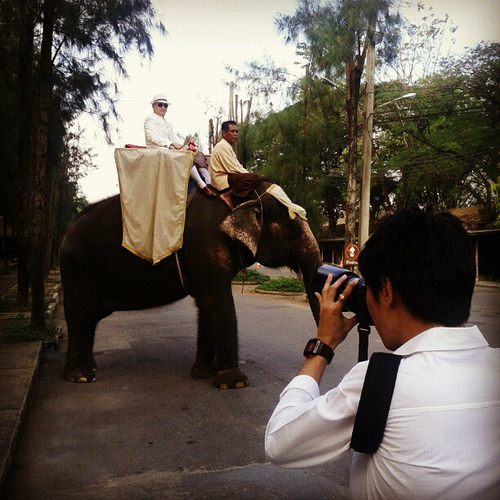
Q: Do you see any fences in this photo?
A: No, there are no fences.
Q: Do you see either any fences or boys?
A: No, there are no fences or boys.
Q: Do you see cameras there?
A: Yes, there is a camera.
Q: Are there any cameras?
A: Yes, there is a camera.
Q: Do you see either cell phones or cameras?
A: Yes, there is a camera.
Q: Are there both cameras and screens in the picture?
A: No, there is a camera but no screens.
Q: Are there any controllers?
A: No, there are no controllers.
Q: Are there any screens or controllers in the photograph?
A: No, there are no controllers or screens.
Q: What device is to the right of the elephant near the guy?
A: The device is a camera.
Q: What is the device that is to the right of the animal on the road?
A: The device is a camera.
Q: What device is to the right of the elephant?
A: The device is a camera.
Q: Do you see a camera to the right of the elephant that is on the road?
A: Yes, there is a camera to the right of the elephant.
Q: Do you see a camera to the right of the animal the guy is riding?
A: Yes, there is a camera to the right of the elephant.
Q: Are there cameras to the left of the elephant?
A: No, the camera is to the right of the elephant.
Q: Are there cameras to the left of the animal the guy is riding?
A: No, the camera is to the right of the elephant.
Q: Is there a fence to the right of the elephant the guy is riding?
A: No, there is a camera to the right of the elephant.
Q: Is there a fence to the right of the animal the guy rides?
A: No, there is a camera to the right of the elephant.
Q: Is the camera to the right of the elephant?
A: Yes, the camera is to the right of the elephant.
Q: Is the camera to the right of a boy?
A: No, the camera is to the right of the elephant.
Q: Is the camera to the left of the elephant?
A: No, the camera is to the right of the elephant.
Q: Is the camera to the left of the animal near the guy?
A: No, the camera is to the right of the elephant.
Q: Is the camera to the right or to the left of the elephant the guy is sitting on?
A: The camera is to the right of the elephant.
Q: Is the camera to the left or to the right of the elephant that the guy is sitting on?
A: The camera is to the right of the elephant.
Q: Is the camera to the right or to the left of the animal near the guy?
A: The camera is to the right of the elephant.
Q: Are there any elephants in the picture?
A: Yes, there is an elephant.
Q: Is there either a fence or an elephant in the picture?
A: Yes, there is an elephant.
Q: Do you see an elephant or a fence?
A: Yes, there is an elephant.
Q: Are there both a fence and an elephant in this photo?
A: No, there is an elephant but no fences.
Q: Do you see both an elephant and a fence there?
A: No, there is an elephant but no fences.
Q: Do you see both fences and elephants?
A: No, there is an elephant but no fences.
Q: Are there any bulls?
A: No, there are no bulls.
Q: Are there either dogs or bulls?
A: No, there are no bulls or dogs.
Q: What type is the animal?
A: The animal is an elephant.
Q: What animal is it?
A: The animal is an elephant.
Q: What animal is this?
A: This is an elephant.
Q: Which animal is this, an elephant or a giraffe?
A: This is an elephant.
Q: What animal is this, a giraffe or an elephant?
A: This is an elephant.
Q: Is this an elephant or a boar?
A: This is an elephant.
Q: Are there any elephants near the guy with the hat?
A: Yes, there is an elephant near the guy.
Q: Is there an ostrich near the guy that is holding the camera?
A: No, there is an elephant near the guy.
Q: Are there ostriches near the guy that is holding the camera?
A: No, there is an elephant near the guy.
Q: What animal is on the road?
A: The elephant is on the road.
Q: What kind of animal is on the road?
A: The animal is an elephant.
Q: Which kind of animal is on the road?
A: The animal is an elephant.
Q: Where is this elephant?
A: The elephant is on the road.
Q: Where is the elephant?
A: The elephant is on the road.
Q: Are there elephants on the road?
A: Yes, there is an elephant on the road.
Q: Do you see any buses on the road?
A: No, there is an elephant on the road.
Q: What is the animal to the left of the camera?
A: The animal is an elephant.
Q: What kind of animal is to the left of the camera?
A: The animal is an elephant.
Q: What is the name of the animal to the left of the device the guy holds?
A: The animal is an elephant.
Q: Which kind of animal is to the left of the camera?
A: The animal is an elephant.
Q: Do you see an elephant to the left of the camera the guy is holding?
A: Yes, there is an elephant to the left of the camera.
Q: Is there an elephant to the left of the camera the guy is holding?
A: Yes, there is an elephant to the left of the camera.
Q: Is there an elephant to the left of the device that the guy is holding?
A: Yes, there is an elephant to the left of the camera.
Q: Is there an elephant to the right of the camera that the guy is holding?
A: No, the elephant is to the left of the camera.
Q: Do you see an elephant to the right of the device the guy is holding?
A: No, the elephant is to the left of the camera.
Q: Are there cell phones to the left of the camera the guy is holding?
A: No, there is an elephant to the left of the camera.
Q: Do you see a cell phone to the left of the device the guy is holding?
A: No, there is an elephant to the left of the camera.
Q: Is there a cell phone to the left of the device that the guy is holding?
A: No, there is an elephant to the left of the camera.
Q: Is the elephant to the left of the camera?
A: Yes, the elephant is to the left of the camera.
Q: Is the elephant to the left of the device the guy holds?
A: Yes, the elephant is to the left of the camera.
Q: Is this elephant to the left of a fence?
A: No, the elephant is to the left of the camera.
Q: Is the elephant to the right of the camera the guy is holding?
A: No, the elephant is to the left of the camera.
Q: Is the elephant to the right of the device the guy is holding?
A: No, the elephant is to the left of the camera.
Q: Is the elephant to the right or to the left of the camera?
A: The elephant is to the left of the camera.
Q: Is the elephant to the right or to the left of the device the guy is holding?
A: The elephant is to the left of the camera.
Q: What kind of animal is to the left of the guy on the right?
A: The animal is an elephant.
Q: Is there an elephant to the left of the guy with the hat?
A: Yes, there is an elephant to the left of the guy.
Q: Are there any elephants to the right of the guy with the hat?
A: No, the elephant is to the left of the guy.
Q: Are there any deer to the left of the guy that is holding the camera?
A: No, there is an elephant to the left of the guy.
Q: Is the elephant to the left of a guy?
A: Yes, the elephant is to the left of a guy.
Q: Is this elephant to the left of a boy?
A: No, the elephant is to the left of a guy.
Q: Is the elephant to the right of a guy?
A: No, the elephant is to the left of a guy.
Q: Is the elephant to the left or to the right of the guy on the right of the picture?
A: The elephant is to the left of the guy.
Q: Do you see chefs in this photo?
A: No, there are no chefs.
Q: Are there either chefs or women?
A: No, there are no chefs or women.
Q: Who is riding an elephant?
A: The guy is riding an elephant.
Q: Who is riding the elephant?
A: The guy is riding an elephant.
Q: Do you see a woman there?
A: No, there are no women.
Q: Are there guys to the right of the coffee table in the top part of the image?
A: Yes, there is a guy to the right of the coffee table.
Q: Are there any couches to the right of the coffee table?
A: No, there is a guy to the right of the coffee table.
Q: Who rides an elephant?
A: The guy rides an elephant.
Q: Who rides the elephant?
A: The guy rides an elephant.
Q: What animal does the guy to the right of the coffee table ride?
A: The guy rides an elephant.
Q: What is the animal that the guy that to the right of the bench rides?
A: The animal is an elephant.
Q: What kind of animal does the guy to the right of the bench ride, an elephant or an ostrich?
A: The guy rides an elephant.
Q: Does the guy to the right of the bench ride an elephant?
A: Yes, the guy rides an elephant.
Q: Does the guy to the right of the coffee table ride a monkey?
A: No, the guy rides an elephant.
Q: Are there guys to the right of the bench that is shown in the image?
A: Yes, there is a guy to the right of the bench.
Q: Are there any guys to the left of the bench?
A: No, the guy is to the right of the bench.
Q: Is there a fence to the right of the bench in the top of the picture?
A: No, there is a guy to the right of the bench.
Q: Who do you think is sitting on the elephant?
A: The guy is sitting on the elephant.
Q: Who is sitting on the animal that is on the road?
A: The guy is sitting on the elephant.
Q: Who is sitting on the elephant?
A: The guy is sitting on the elephant.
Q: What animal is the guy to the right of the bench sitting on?
A: The guy is sitting on the elephant.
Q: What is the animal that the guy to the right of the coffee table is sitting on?
A: The animal is an elephant.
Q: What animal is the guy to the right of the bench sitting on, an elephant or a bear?
A: The guy is sitting on an elephant.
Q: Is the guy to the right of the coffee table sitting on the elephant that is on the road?
A: Yes, the guy is sitting on the elephant.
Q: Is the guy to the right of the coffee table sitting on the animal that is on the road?
A: Yes, the guy is sitting on the elephant.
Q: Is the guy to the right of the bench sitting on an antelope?
A: No, the guy is sitting on the elephant.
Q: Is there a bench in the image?
A: Yes, there is a bench.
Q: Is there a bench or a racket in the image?
A: Yes, there is a bench.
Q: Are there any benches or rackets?
A: Yes, there is a bench.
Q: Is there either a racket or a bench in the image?
A: Yes, there is a bench.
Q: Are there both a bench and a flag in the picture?
A: No, there is a bench but no flags.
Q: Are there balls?
A: No, there are no balls.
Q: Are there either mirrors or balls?
A: No, there are no balls or mirrors.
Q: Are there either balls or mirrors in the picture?
A: No, there are no balls or mirrors.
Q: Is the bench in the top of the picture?
A: Yes, the bench is in the top of the image.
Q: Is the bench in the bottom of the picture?
A: No, the bench is in the top of the image.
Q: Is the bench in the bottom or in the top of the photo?
A: The bench is in the top of the image.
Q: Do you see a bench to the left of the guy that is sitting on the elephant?
A: Yes, there is a bench to the left of the guy.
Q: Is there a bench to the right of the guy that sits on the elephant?
A: No, the bench is to the left of the guy.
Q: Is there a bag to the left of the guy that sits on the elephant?
A: No, there is a bench to the left of the guy.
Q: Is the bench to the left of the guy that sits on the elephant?
A: Yes, the bench is to the left of the guy.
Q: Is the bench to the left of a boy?
A: No, the bench is to the left of the guy.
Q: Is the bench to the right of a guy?
A: No, the bench is to the left of a guy.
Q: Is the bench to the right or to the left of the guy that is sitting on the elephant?
A: The bench is to the left of the guy.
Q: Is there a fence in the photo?
A: No, there are no fences.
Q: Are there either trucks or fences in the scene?
A: No, there are no fences or trucks.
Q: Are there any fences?
A: No, there are no fences.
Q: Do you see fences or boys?
A: No, there are no fences or boys.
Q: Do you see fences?
A: No, there are no fences.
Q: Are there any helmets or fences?
A: No, there are no fences or helmets.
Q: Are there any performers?
A: No, there are no performers.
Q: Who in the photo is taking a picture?
A: The guy is taking a picture.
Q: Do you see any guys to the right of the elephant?
A: Yes, there is a guy to the right of the elephant.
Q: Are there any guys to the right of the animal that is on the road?
A: Yes, there is a guy to the right of the elephant.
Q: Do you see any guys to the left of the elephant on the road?
A: No, the guy is to the right of the elephant.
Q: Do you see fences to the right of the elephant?
A: No, there is a guy to the right of the elephant.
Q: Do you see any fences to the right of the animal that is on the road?
A: No, there is a guy to the right of the elephant.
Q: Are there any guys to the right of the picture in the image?
A: Yes, there is a guy to the right of the picture.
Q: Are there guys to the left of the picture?
A: No, the guy is to the right of the picture.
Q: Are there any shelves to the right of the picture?
A: No, there is a guy to the right of the picture.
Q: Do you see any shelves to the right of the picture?
A: No, there is a guy to the right of the picture.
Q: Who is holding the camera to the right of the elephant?
A: The guy is holding the camera.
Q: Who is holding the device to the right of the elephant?
A: The guy is holding the camera.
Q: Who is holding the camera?
A: The guy is holding the camera.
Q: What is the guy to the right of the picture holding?
A: The guy is holding the camera.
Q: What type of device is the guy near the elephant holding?
A: The guy is holding the camera.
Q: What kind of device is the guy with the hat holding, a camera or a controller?
A: The guy is holding a camera.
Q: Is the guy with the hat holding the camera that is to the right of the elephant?
A: Yes, the guy is holding the camera.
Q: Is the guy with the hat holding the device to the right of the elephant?
A: Yes, the guy is holding the camera.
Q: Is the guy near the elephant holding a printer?
A: No, the guy is holding the camera.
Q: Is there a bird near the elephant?
A: No, there is a guy near the elephant.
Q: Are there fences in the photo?
A: No, there are no fences.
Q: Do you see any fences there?
A: No, there are no fences.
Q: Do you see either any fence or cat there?
A: No, there are no fences or cats.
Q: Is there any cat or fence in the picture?
A: No, there are no fences or cats.